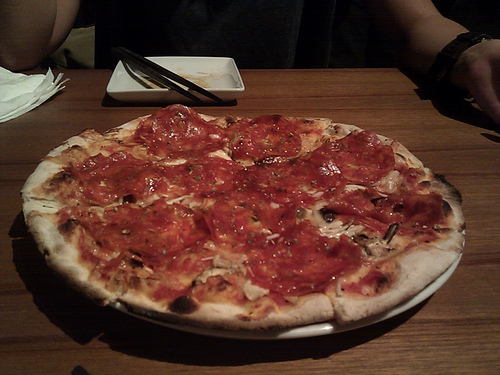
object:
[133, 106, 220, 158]
pepperoni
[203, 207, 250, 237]
topping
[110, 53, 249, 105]
bowl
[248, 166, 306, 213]
topping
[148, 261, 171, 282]
topping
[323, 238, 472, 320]
crust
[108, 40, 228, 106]
chopsticks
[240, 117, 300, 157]
pepperoni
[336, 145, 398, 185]
pepperoni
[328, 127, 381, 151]
pepperoni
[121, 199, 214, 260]
pepperoni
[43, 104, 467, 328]
baked pizza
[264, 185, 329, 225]
topping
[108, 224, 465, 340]
plate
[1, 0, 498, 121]
person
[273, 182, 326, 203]
topping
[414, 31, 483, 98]
watch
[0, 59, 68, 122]
paper towel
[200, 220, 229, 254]
topping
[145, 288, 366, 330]
crust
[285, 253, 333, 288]
topping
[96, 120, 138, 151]
cheese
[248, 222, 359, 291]
pepperoni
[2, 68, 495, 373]
table